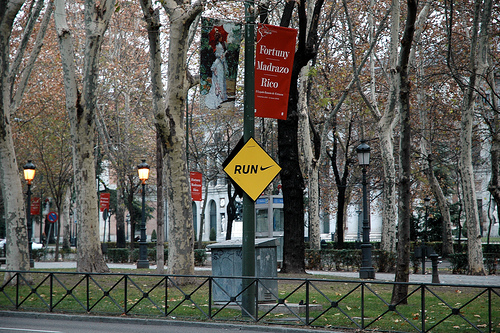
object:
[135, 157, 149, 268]
lamp post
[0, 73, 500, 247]
buidling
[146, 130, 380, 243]
white building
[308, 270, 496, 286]
sideway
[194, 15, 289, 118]
flags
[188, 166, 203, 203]
flags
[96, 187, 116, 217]
flags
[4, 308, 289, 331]
street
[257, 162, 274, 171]
logo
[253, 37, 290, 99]
white lettering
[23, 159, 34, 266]
street light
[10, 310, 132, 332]
road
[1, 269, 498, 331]
fence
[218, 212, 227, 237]
statue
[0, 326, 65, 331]
stripe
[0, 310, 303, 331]
road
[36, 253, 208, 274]
path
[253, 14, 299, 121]
banner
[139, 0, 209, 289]
tall tree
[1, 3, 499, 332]
park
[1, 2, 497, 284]
trees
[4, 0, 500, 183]
brown leaves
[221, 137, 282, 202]
advertisement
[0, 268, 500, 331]
railing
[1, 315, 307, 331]
path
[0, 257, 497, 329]
gate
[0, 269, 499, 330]
guard rail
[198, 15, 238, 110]
sign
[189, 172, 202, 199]
sign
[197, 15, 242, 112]
sign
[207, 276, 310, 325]
gate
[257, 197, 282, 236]
booth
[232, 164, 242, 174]
letter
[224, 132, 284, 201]
sign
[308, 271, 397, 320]
grass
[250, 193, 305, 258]
phone booth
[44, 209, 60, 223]
street sign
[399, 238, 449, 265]
bush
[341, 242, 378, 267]
bush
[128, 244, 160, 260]
bush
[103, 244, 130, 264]
bush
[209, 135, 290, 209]
street sign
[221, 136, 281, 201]
yellow sign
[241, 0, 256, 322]
black pole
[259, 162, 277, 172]
symbol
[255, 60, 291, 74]
lettering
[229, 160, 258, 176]
writing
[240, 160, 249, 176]
letter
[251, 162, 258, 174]
letter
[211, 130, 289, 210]
sign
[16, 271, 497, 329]
leaves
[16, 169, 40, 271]
pole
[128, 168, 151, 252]
pole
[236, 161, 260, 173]
run